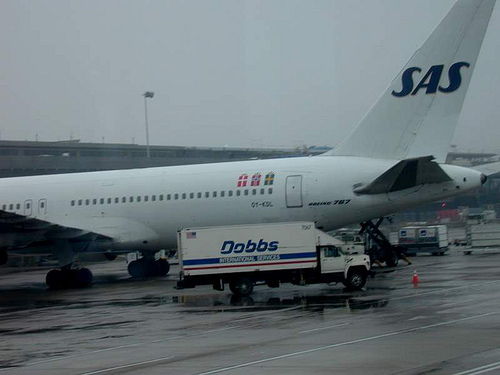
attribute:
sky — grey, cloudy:
[7, 3, 498, 147]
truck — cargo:
[173, 223, 379, 298]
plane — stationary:
[0, 9, 495, 297]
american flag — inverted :
[183, 230, 203, 248]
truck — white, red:
[175, 222, 445, 307]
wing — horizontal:
[0, 203, 162, 267]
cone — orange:
[412, 269, 419, 285]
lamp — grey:
[142, 91, 154, 158]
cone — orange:
[412, 270, 419, 281]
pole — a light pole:
[138, 87, 159, 160]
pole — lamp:
[136, 89, 156, 166]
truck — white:
[176, 222, 337, 288]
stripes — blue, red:
[206, 255, 262, 267]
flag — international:
[261, 167, 276, 189]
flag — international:
[251, 170, 262, 190]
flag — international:
[232, 173, 249, 191]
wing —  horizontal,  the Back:
[348, 152, 455, 196]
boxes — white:
[396, 225, 434, 240]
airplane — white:
[0, 2, 496, 292]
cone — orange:
[407, 264, 422, 287]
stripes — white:
[411, 270, 419, 277]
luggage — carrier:
[394, 221, 453, 256]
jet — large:
[4, 3, 485, 271]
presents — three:
[232, 170, 276, 190]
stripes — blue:
[167, 225, 359, 293]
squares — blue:
[397, 222, 435, 246]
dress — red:
[407, 270, 423, 289]